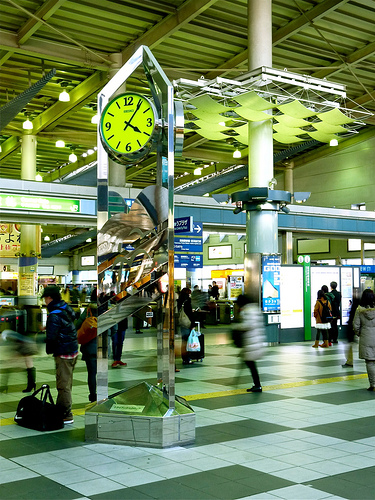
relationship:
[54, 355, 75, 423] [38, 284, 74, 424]
legs on person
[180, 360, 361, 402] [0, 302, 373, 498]
stripe on floor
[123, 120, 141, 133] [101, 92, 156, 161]
hand of a clock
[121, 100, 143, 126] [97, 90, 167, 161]
minute hand of a clock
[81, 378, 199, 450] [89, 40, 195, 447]
base of glass stand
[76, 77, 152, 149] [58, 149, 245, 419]
clock on stand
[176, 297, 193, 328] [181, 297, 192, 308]
bag on shoulder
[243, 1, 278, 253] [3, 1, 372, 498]
pillar of building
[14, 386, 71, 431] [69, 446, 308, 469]
bag on ground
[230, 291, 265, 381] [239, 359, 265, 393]
person has leg